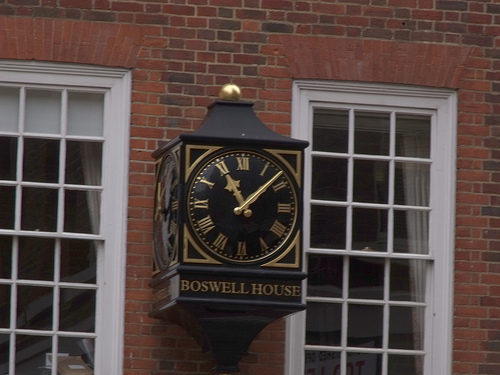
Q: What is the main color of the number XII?
A: Yellow.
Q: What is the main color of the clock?
A: Black.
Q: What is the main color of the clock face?
A: Black.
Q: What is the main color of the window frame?
A: White.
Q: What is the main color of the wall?
A: Red.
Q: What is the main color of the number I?
A: Gold.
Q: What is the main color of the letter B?
A: Gold.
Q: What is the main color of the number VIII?
A: Gold.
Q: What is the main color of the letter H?
A: Gold.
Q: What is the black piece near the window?
A: A clock.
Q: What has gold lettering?
A: Clock.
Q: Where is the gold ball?
A: On top clock.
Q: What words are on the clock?
A: Boswell house.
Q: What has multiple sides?
A: Clock.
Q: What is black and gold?
A: Ornate clock.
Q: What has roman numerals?
A: Clock.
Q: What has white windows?
A: Brick building.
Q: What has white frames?
A: Windows.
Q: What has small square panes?
A: Window.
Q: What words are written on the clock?
A: Boswell House.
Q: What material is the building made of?
A: Brick.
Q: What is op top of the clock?
A: Golden ball.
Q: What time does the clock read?
A: 11:07.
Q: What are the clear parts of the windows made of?
A: Glass.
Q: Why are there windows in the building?
A: To look out.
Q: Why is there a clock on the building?
A: To tell time.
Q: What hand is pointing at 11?
A: Short.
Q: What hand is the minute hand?
A: Long.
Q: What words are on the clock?
A: Boswell House.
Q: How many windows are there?
A: Two.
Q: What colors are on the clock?
A: Black and gold.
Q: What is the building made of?
A: Bricks.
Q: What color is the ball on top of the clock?
A: Gold.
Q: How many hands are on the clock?
A: Two.